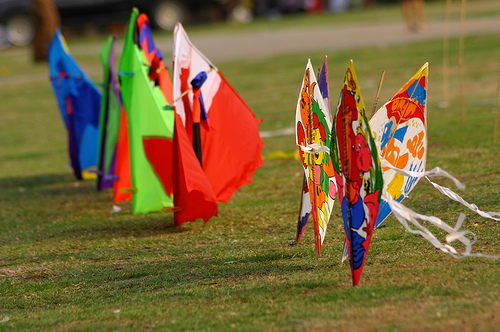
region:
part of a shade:
[214, 250, 264, 315]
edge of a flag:
[351, 252, 368, 297]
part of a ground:
[211, 222, 274, 294]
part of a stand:
[183, 109, 219, 206]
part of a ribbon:
[385, 190, 423, 267]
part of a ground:
[216, 250, 270, 309]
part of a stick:
[446, 37, 466, 92]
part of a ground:
[361, 281, 404, 317]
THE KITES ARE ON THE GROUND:
[46, 6, 498, 298]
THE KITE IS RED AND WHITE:
[163, 16, 268, 235]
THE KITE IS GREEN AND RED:
[122, 6, 183, 218]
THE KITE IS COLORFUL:
[291, 62, 346, 263]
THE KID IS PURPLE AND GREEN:
[95, 27, 125, 197]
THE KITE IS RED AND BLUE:
[110, 12, 190, 214]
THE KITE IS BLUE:
[37, 23, 109, 191]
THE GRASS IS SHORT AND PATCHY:
[0, 27, 499, 330]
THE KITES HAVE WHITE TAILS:
[362, 152, 498, 266]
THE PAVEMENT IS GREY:
[0, 12, 499, 91]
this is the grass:
[112, 241, 217, 295]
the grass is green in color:
[148, 251, 233, 321]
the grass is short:
[91, 250, 196, 325]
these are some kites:
[48, 14, 453, 266]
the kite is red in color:
[221, 110, 242, 153]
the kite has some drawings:
[321, 134, 366, 182]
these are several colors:
[332, 131, 404, 183]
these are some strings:
[388, 164, 486, 273]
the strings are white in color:
[388, 159, 499, 265]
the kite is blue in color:
[46, 55, 63, 67]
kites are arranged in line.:
[32, 34, 469, 231]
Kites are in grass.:
[39, 56, 429, 245]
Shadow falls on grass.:
[24, 176, 141, 298]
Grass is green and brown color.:
[39, 216, 193, 323]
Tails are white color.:
[392, 158, 491, 265]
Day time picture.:
[23, 27, 479, 282]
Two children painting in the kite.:
[298, 110, 338, 184]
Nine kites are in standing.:
[1, 18, 466, 285]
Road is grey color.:
[215, 26, 359, 52]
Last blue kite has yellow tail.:
[60, 122, 102, 203]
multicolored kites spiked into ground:
[273, 42, 446, 269]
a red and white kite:
[152, 29, 254, 253]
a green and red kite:
[90, 27, 180, 223]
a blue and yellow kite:
[36, 24, 96, 192]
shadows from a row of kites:
[7, 185, 346, 311]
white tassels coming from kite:
[394, 150, 480, 279]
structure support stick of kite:
[300, 64, 325, 259]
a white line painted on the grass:
[247, 92, 315, 150]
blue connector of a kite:
[183, 61, 221, 106]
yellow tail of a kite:
[257, 135, 316, 200]